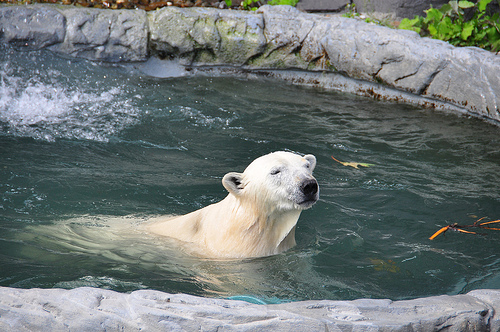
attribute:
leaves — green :
[398, 0, 498, 48]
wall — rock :
[294, 2, 441, 34]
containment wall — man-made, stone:
[1, 2, 498, 124]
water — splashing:
[6, 45, 184, 142]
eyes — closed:
[270, 159, 312, 176]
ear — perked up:
[216, 171, 246, 194]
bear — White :
[223, 158, 318, 243]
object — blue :
[225, 290, 287, 306]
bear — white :
[222, 147, 320, 255]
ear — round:
[221, 171, 241, 193]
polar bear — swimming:
[75, 140, 325, 267]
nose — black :
[298, 179, 318, 200]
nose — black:
[295, 178, 321, 196]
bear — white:
[18, 150, 325, 307]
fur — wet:
[150, 143, 323, 258]